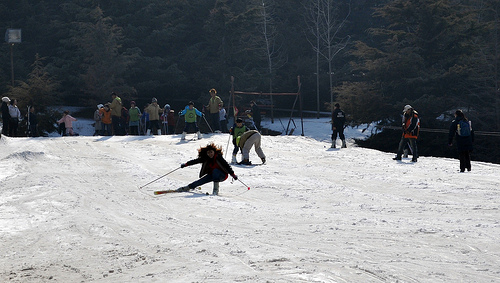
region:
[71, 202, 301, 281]
Markings in the white snow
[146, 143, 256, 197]
A woman crouching down on skis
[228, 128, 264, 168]
A man bending down to pick something up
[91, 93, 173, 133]
People standing in a group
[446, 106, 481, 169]
A woman with a blue backpack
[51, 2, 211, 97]
Tall pine trees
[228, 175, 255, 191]
A silver ski pole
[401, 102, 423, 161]
A man wearing an orange and black jacket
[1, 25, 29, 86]
A tall light post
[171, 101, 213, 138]
A child on skis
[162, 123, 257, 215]
person is on skis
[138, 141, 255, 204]
person holds ski poles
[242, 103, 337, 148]
white fence behind people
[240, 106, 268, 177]
people are bending down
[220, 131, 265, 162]
people in front of skier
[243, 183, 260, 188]
orange tips on ski poles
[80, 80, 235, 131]
people are watching skiers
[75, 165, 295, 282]
tracks made in snow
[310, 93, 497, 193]
people standing off to side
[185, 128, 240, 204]
skier's hair is flying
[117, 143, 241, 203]
a person skiing on the snow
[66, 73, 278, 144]
several people standing in the snow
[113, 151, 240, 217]
a person holding ski poles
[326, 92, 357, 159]
a person wearing black clothes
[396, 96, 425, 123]
a person wearing a white hat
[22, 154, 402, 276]
snow on the ground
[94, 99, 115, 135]
a person wearing a orange jacket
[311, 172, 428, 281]
tracks in the snow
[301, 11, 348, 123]
a tall tree with no leaves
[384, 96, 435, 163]
a person wearing a red and black jacket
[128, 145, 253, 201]
a skier going downhill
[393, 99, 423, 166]
a man walking in snow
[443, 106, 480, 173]
a man walking in snow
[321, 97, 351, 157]
a man walking in snow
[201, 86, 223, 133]
a man walking in snow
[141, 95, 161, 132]
a man walking in snow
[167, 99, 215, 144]
a skier going downhill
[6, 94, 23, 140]
a man walking in snow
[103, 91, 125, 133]
a man walking in snow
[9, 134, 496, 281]
a large ski slope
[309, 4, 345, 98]
Large brown tree without leaves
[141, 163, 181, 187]
Black ski trak pole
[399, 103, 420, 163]
Man walking wearing orange and black coat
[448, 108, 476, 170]
Woman wearing blue backpack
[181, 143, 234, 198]
Woman falling in snow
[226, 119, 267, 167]
Guy putting ski on child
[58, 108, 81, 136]
Girl wearing pink coat running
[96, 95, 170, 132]
Group of people waiting to ski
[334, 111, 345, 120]
White wrighting on back of coat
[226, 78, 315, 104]
Long brown wood tripod